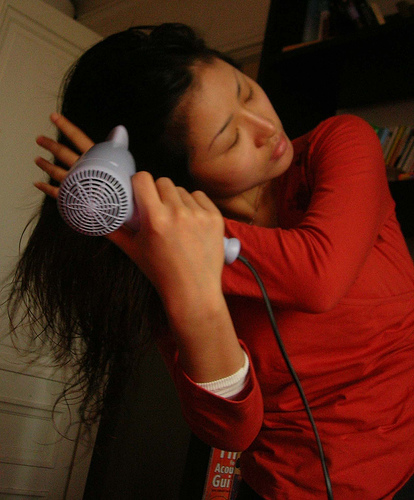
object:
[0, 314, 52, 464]
door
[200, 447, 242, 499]
book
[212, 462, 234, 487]
lettering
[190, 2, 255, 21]
white wall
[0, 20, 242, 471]
long hair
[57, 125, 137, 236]
blow dryer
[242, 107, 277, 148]
nose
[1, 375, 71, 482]
drawers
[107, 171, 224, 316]
hand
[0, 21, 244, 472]
hair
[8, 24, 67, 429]
door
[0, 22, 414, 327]
girl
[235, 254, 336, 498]
cord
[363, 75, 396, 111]
ground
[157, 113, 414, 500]
shirt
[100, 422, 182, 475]
bookcase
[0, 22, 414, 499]
woman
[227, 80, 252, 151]
eyes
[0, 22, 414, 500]
girl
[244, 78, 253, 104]
eye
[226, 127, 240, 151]
eye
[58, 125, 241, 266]
blow dryer